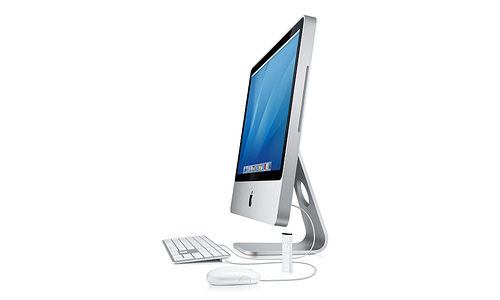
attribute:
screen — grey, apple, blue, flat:
[226, 43, 335, 201]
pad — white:
[178, 232, 209, 266]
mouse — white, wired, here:
[206, 262, 247, 299]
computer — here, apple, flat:
[248, 42, 322, 195]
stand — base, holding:
[290, 183, 345, 263]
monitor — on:
[229, 73, 287, 129]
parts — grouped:
[221, 167, 329, 298]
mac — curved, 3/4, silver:
[236, 52, 361, 193]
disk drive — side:
[302, 65, 314, 135]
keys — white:
[197, 239, 228, 253]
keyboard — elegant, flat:
[170, 219, 228, 269]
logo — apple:
[229, 184, 257, 210]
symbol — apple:
[229, 186, 272, 212]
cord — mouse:
[291, 210, 322, 241]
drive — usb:
[283, 228, 314, 275]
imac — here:
[163, 44, 406, 262]